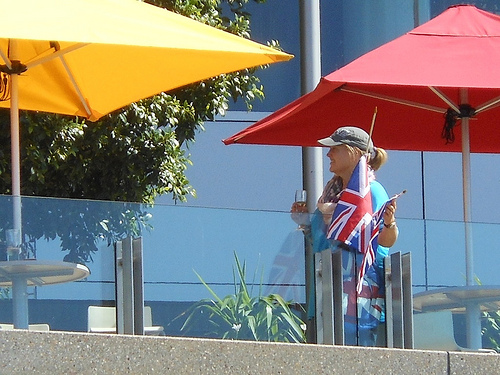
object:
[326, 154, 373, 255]
flags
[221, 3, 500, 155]
umbrella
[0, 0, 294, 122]
umbrella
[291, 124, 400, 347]
woman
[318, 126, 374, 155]
baseball cap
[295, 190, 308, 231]
champagne flute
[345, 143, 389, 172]
hair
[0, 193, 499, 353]
barrier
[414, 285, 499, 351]
table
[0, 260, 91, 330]
table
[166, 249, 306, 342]
plant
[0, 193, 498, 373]
patio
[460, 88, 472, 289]
pole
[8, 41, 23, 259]
pole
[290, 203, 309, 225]
hand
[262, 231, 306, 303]
reflection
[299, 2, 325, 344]
post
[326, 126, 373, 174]
head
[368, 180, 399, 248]
arm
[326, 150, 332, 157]
nose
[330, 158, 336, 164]
mouth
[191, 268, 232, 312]
leaf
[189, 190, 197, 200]
leaf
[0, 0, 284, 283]
tree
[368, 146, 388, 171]
pony tail